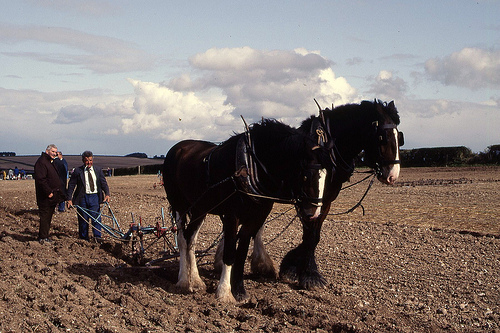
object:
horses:
[278, 103, 403, 290]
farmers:
[65, 152, 112, 236]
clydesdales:
[165, 120, 319, 305]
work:
[72, 196, 191, 264]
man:
[35, 144, 71, 240]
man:
[71, 149, 113, 234]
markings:
[312, 166, 326, 221]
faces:
[368, 101, 402, 171]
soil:
[34, 222, 286, 305]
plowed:
[64, 196, 190, 263]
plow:
[74, 198, 180, 269]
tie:
[84, 167, 98, 193]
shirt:
[84, 166, 96, 194]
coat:
[73, 166, 108, 199]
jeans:
[78, 194, 101, 242]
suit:
[67, 165, 112, 209]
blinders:
[373, 127, 385, 145]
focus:
[324, 158, 336, 171]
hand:
[46, 190, 56, 199]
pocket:
[45, 189, 67, 201]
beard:
[50, 154, 60, 161]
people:
[34, 143, 111, 240]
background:
[51, 60, 188, 266]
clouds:
[141, 50, 328, 134]